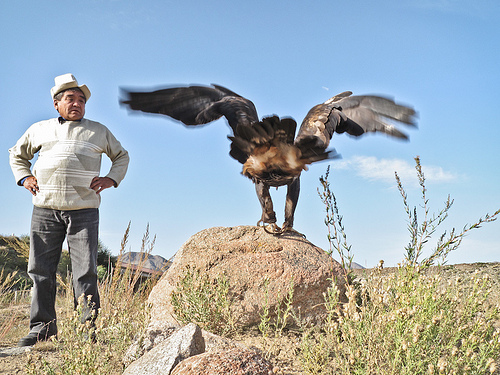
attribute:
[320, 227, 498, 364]
plant — live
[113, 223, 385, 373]
rocky area — pictured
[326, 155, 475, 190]
cloud — white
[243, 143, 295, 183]
face — unseen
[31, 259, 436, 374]
desert — pictured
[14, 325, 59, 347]
shoe — black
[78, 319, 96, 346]
shoe — black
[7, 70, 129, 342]
man — old 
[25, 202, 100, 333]
jeans — grey , dark 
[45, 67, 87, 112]
hat — beige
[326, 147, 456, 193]
cloud — small , white 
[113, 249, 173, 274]
mountain — tall 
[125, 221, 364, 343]
rock — large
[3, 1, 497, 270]
sky — blue , clear 